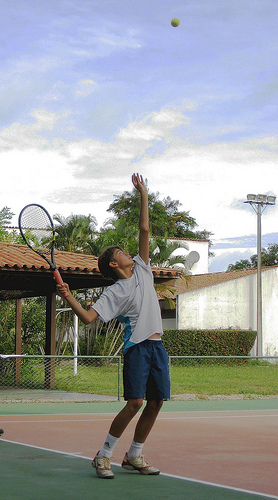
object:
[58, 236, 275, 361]
white building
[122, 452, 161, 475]
shoe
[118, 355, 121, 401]
pole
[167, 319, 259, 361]
bush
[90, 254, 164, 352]
gray shirt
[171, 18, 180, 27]
ball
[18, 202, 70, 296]
racket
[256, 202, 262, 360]
pole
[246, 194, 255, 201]
light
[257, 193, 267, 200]
light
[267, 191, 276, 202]
light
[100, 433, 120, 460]
sock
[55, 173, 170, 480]
boy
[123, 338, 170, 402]
blue shorts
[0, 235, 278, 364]
building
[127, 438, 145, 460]
sock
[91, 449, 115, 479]
shoe